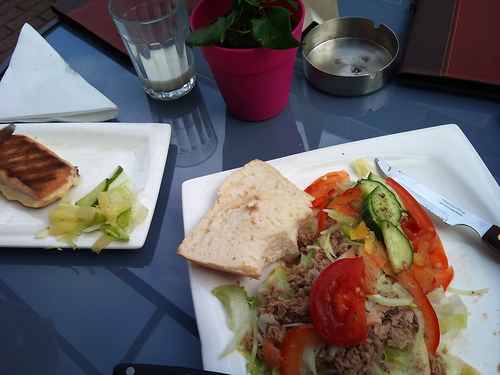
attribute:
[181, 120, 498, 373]
plate — square, white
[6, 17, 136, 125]
napkin — white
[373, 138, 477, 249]
knife — silver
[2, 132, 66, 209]
sandwich — grilled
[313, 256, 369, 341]
tomato slice — red